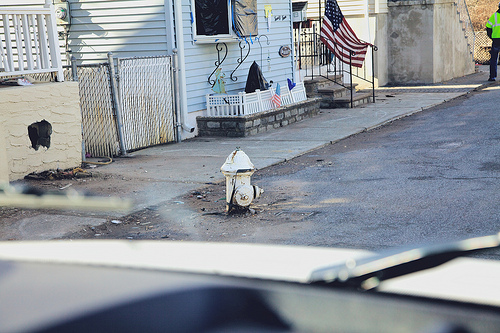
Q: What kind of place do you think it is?
A: It is a road.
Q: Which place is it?
A: It is a road.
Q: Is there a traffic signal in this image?
A: No, there are no traffic lights.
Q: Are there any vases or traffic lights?
A: No, there are no traffic lights or vases.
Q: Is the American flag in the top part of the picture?
A: Yes, the American flag is in the top of the image.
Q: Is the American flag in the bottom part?
A: No, the American flag is in the top of the image.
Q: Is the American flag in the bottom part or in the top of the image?
A: The American flag is in the top of the image.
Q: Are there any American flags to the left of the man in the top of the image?
A: Yes, there is an American flag to the left of the man.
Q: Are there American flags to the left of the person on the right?
A: Yes, there is an American flag to the left of the man.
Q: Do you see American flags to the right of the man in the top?
A: No, the American flag is to the left of the man.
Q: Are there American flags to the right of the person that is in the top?
A: No, the American flag is to the left of the man.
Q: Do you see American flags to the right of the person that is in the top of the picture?
A: No, the American flag is to the left of the man.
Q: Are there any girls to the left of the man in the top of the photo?
A: No, there is an American flag to the left of the man.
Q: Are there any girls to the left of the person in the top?
A: No, there is an American flag to the left of the man.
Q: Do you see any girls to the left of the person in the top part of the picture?
A: No, there is an American flag to the left of the man.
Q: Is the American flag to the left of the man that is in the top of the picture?
A: Yes, the American flag is to the left of the man.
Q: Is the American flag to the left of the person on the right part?
A: Yes, the American flag is to the left of the man.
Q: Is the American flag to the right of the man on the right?
A: No, the American flag is to the left of the man.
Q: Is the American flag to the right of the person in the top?
A: No, the American flag is to the left of the man.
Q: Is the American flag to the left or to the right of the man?
A: The American flag is to the left of the man.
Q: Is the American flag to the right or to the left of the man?
A: The American flag is to the left of the man.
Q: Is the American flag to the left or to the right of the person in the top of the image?
A: The American flag is to the left of the man.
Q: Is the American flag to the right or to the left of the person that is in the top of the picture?
A: The American flag is to the left of the man.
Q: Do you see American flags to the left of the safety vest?
A: Yes, there is an American flag to the left of the safety vest.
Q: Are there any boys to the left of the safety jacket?
A: No, there is an American flag to the left of the safety jacket.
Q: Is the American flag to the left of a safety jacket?
A: Yes, the American flag is to the left of a safety jacket.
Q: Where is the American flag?
A: The American flag is on the porch.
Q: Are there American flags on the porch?
A: Yes, there is an American flag on the porch.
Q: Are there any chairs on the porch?
A: No, there is an American flag on the porch.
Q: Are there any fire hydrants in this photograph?
A: Yes, there is a fire hydrant.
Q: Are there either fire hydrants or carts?
A: Yes, there is a fire hydrant.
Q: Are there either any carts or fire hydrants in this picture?
A: Yes, there is a fire hydrant.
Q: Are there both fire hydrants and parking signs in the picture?
A: No, there is a fire hydrant but no parking signs.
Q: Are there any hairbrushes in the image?
A: No, there are no hairbrushes.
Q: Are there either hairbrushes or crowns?
A: No, there are no hairbrushes or crowns.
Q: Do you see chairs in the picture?
A: No, there are no chairs.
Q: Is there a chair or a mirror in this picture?
A: No, there are no chairs or mirrors.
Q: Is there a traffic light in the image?
A: No, there are no traffic lights.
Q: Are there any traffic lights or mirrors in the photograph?
A: No, there are no traffic lights or mirrors.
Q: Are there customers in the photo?
A: No, there are no customers.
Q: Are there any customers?
A: No, there are no customers.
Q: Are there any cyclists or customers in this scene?
A: No, there are no customers or cyclists.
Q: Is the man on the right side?
A: Yes, the man is on the right of the image.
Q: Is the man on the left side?
A: No, the man is on the right of the image.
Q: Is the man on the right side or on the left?
A: The man is on the right of the image.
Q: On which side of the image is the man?
A: The man is on the right of the image.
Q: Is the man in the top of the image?
A: Yes, the man is in the top of the image.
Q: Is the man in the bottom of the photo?
A: No, the man is in the top of the image.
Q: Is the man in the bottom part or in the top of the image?
A: The man is in the top of the image.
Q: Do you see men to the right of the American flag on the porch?
A: Yes, there is a man to the right of the American flag.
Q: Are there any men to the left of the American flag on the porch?
A: No, the man is to the right of the American flag.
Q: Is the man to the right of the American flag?
A: Yes, the man is to the right of the American flag.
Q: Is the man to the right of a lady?
A: No, the man is to the right of the American flag.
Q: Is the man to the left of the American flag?
A: No, the man is to the right of the American flag.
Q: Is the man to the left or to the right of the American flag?
A: The man is to the right of the American flag.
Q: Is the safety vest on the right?
A: Yes, the safety vest is on the right of the image.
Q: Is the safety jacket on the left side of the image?
A: No, the safety jacket is on the right of the image.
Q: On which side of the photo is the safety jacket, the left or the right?
A: The safety jacket is on the right of the image.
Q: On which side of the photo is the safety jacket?
A: The safety jacket is on the right of the image.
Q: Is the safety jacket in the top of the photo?
A: Yes, the safety jacket is in the top of the image.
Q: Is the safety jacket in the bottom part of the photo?
A: No, the safety jacket is in the top of the image.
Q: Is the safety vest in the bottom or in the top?
A: The safety vest is in the top of the image.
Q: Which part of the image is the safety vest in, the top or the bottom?
A: The safety vest is in the top of the image.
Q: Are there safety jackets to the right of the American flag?
A: Yes, there is a safety jacket to the right of the American flag.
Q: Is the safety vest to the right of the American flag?
A: Yes, the safety vest is to the right of the American flag.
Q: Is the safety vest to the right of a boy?
A: No, the safety vest is to the right of the American flag.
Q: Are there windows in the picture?
A: Yes, there is a window.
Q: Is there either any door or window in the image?
A: Yes, there is a window.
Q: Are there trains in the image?
A: No, there are no trains.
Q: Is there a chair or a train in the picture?
A: No, there are no trains or chairs.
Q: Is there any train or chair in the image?
A: No, there are no trains or chairs.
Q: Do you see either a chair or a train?
A: No, there are no trains or chairs.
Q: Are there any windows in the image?
A: Yes, there is a window.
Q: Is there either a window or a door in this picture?
A: Yes, there is a window.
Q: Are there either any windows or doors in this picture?
A: Yes, there is a window.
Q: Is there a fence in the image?
A: Yes, there is a fence.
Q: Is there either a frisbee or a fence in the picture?
A: Yes, there is a fence.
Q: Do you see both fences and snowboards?
A: No, there is a fence but no snowboards.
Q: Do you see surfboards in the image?
A: No, there are no surfboards.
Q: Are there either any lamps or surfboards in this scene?
A: No, there are no surfboards or lamps.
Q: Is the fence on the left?
A: Yes, the fence is on the left of the image.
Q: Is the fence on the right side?
A: No, the fence is on the left of the image.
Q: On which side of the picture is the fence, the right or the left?
A: The fence is on the left of the image.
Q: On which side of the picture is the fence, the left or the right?
A: The fence is on the left of the image.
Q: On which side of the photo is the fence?
A: The fence is on the left of the image.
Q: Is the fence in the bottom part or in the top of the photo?
A: The fence is in the top of the image.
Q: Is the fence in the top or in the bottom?
A: The fence is in the top of the image.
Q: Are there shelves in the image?
A: No, there are no shelves.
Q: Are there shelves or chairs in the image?
A: No, there are no shelves or chairs.